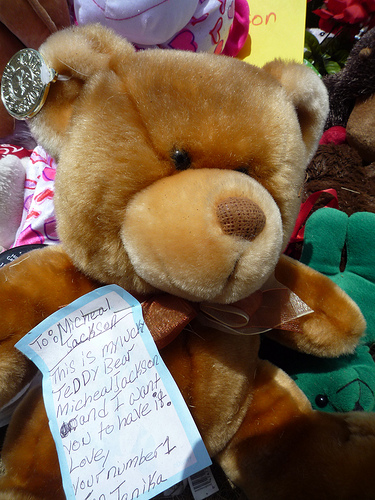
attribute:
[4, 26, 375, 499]
teddy bear — brown, large, fuzzy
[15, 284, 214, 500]
note — blue, handwritten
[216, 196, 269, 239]
nose — brown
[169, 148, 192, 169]
eye — black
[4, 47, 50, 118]
medallion — silver, gold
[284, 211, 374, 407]
green bear — upside down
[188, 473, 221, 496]
bar code — black, white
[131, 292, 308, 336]
ribbon — brown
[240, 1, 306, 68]
note — yellow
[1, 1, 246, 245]
teddy bear — purple